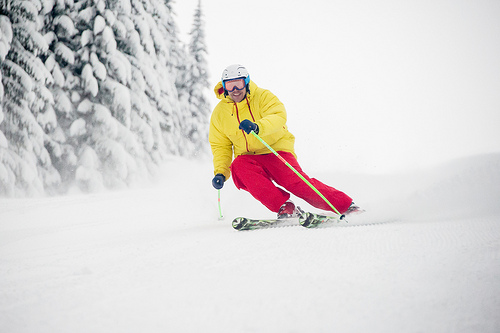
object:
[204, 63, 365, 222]
man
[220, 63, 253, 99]
helmet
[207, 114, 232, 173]
right arm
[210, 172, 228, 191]
right hand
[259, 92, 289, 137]
left arm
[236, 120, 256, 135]
left hand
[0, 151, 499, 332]
snow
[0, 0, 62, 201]
tree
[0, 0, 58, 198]
snow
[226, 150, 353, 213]
pants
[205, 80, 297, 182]
sweatshirt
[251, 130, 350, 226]
ski pole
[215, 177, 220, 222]
ski pole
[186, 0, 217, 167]
tree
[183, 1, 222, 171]
snow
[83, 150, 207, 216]
snow dust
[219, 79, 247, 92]
ski goggles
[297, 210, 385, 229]
skis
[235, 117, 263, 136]
glove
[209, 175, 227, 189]
glove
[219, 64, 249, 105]
head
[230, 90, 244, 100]
mouth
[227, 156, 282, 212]
leg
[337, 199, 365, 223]
foot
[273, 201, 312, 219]
foot